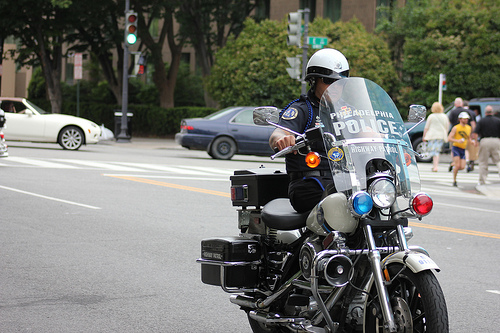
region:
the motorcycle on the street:
[197, 77, 460, 331]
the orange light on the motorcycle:
[304, 151, 320, 167]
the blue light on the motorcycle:
[352, 193, 374, 215]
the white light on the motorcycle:
[372, 179, 397, 207]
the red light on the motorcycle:
[411, 193, 433, 215]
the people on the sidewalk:
[422, 96, 498, 186]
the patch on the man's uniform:
[280, 107, 297, 119]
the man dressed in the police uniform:
[268, 48, 389, 317]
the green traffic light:
[127, 34, 137, 43]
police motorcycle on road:
[217, 44, 463, 326]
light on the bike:
[353, 193, 377, 218]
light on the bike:
[411, 195, 431, 220]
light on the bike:
[372, 175, 392, 210]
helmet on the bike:
[300, 48, 350, 76]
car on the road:
[6, 98, 117, 158]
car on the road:
[187, 98, 304, 164]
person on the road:
[453, 107, 468, 191]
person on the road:
[421, 106, 443, 169]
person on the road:
[476, 99, 496, 185]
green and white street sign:
[305, 29, 327, 49]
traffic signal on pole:
[285, 6, 300, 45]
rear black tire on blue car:
[214, 131, 241, 161]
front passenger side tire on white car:
[60, 122, 87, 152]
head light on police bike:
[375, 170, 396, 215]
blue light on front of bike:
[351, 184, 373, 218]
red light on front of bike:
[405, 191, 435, 214]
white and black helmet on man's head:
[303, 47, 350, 80]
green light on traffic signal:
[122, 6, 143, 51]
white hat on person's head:
[458, 109, 470, 120]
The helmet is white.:
[284, 34, 353, 84]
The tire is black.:
[356, 244, 453, 327]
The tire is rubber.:
[363, 253, 458, 330]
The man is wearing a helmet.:
[306, 37, 357, 92]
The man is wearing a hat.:
[449, 107, 486, 132]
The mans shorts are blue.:
[448, 147, 470, 157]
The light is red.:
[409, 188, 438, 218]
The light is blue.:
[346, 185, 372, 216]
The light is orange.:
[300, 145, 322, 175]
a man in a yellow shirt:
[448, 112, 473, 185]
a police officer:
[211, 51, 418, 252]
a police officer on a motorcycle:
[221, 70, 471, 325]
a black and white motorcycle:
[204, 189, 411, 326]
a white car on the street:
[7, 91, 114, 145]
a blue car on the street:
[175, 85, 275, 162]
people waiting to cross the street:
[421, 93, 498, 161]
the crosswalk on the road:
[6, 145, 233, 184]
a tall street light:
[120, 10, 142, 137]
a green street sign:
[305, 33, 333, 47]